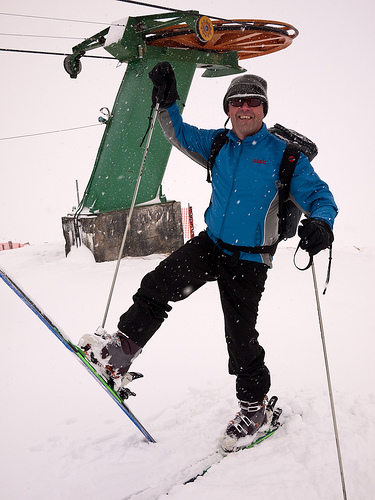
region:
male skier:
[178, 68, 333, 403]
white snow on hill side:
[11, 436, 57, 456]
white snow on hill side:
[23, 384, 45, 416]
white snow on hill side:
[256, 468, 301, 498]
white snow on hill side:
[173, 369, 224, 419]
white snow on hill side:
[266, 308, 299, 345]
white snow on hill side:
[291, 40, 325, 81]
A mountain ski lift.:
[60, 9, 298, 262]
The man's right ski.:
[0, 268, 157, 443]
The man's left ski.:
[121, 413, 301, 499]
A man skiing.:
[77, 63, 338, 453]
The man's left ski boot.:
[219, 395, 280, 450]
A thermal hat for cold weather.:
[222, 73, 267, 115]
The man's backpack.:
[205, 122, 318, 238]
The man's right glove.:
[146, 60, 179, 108]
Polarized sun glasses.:
[229, 97, 264, 107]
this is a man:
[6, 49, 358, 487]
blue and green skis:
[10, 271, 172, 466]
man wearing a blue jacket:
[153, 79, 359, 271]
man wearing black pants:
[95, 187, 290, 412]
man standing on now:
[102, 66, 308, 483]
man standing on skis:
[6, 232, 319, 491]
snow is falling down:
[82, 60, 281, 405]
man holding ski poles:
[81, 71, 358, 496]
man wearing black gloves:
[295, 209, 339, 272]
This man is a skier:
[91, 68, 336, 448]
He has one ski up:
[6, 258, 159, 464]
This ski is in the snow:
[130, 378, 303, 496]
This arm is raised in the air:
[126, 58, 222, 177]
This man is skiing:
[85, 63, 307, 465]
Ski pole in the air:
[78, 85, 172, 356]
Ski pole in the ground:
[301, 249, 354, 499]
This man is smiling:
[211, 81, 268, 136]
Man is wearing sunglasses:
[210, 90, 274, 116]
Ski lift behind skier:
[34, 10, 319, 250]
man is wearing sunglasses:
[215, 65, 276, 135]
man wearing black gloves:
[132, 58, 336, 257]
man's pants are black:
[112, 231, 275, 409]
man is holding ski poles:
[88, 63, 370, 499]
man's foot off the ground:
[79, 312, 148, 396]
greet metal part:
[83, 7, 248, 207]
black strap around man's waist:
[211, 229, 279, 263]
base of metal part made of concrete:
[63, 200, 188, 258]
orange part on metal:
[195, 12, 218, 42]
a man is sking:
[160, 67, 360, 365]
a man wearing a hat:
[151, 72, 292, 241]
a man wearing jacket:
[187, 102, 291, 219]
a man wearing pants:
[192, 222, 302, 417]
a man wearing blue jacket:
[184, 115, 285, 229]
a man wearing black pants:
[127, 207, 294, 414]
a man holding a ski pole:
[243, 238, 370, 384]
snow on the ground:
[262, 455, 328, 498]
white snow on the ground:
[272, 405, 358, 497]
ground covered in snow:
[283, 447, 348, 484]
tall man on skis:
[75, 60, 342, 452]